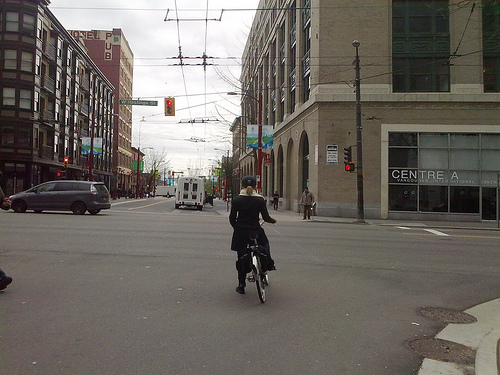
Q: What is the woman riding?
A: Bike.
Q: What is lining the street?
A: A row of buildings.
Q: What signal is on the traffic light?
A: Stop.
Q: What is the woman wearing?
A: A black coat.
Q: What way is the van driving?
A: Left.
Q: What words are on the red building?
A: Hotel Pub.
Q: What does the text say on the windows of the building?
A: Centre A.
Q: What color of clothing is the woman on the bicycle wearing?
A: Black.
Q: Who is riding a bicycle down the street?
A: A woman.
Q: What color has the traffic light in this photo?
A: Red.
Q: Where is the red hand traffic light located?
A: On the power pole.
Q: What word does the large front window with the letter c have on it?
A: Centre.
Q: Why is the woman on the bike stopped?
A: She is at a red light.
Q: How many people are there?
A: 1.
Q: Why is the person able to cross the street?
A: There is no traffic coming.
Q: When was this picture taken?
A: Daytime.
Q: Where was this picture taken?
A: City.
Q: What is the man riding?
A: A bicycle.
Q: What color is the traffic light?
A: Red.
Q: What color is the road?
A: Dark grey.